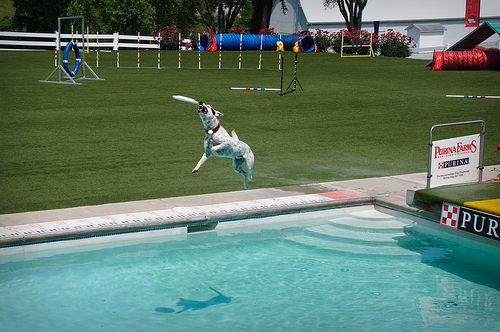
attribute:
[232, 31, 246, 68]
pole — white, red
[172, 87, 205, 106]
frisbee — white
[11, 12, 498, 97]
obstacle course — small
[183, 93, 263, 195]
dog — white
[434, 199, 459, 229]
sign — red, white, plaid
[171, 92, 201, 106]
frisbee — small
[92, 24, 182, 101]
pole — white, red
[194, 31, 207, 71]
pole — red, white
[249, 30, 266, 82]
pole — red, white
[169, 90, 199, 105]
frisbee — white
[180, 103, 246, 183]
dog — small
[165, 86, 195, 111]
frisbee — small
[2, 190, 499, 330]
pool — blue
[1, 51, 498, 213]
green grass — short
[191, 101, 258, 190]
dog — in mid air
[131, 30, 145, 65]
pole — red, white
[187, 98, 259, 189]
dog — small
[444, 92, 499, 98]
pole — white, red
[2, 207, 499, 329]
pool — large, light blue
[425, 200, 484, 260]
sign — black